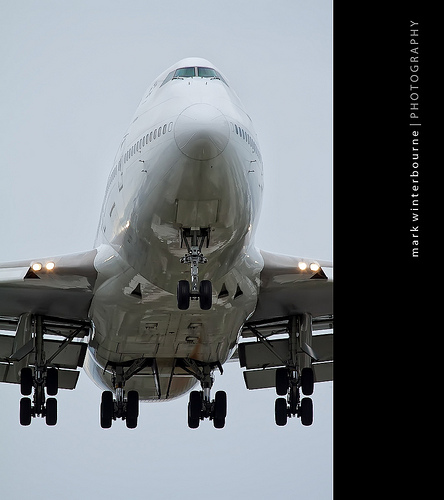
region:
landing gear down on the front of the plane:
[166, 229, 217, 316]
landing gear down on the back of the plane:
[17, 368, 315, 425]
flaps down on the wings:
[238, 337, 280, 395]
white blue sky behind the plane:
[70, 430, 238, 487]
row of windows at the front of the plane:
[114, 116, 172, 161]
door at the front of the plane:
[109, 137, 131, 193]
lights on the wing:
[25, 253, 64, 284]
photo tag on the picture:
[400, 12, 434, 263]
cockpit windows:
[170, 61, 220, 83]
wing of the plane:
[268, 251, 338, 377]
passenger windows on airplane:
[112, 111, 174, 174]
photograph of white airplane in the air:
[4, 65, 329, 429]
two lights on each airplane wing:
[20, 253, 321, 288]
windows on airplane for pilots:
[163, 58, 225, 83]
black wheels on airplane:
[17, 276, 333, 440]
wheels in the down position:
[15, 269, 333, 445]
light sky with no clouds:
[26, 31, 98, 222]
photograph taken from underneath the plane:
[13, 36, 321, 469]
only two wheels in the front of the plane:
[152, 212, 233, 317]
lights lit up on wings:
[13, 246, 328, 287]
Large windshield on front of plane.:
[167, 61, 238, 88]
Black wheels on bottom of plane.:
[9, 365, 78, 452]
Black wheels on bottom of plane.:
[106, 383, 147, 423]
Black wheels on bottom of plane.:
[176, 385, 240, 433]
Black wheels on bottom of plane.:
[268, 366, 317, 438]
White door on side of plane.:
[88, 154, 134, 191]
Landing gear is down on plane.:
[23, 297, 324, 447]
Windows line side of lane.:
[84, 114, 191, 160]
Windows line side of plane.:
[233, 115, 287, 185]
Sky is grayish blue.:
[97, 449, 270, 490]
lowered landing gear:
[9, 353, 324, 449]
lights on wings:
[8, 260, 320, 286]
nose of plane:
[182, 97, 230, 155]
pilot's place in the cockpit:
[150, 61, 227, 104]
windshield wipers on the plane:
[168, 64, 229, 88]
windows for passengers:
[59, 118, 176, 253]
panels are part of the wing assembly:
[4, 311, 87, 399]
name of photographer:
[404, 9, 423, 266]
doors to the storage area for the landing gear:
[142, 363, 197, 408]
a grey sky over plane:
[6, 11, 332, 497]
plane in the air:
[0, 49, 334, 437]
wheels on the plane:
[181, 388, 229, 433]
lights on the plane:
[23, 263, 64, 275]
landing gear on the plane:
[161, 228, 230, 314]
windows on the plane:
[169, 62, 226, 83]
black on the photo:
[365, 381, 427, 471]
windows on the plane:
[123, 134, 169, 155]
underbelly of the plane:
[141, 313, 201, 346]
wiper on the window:
[169, 76, 183, 81]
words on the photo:
[399, 12, 433, 267]